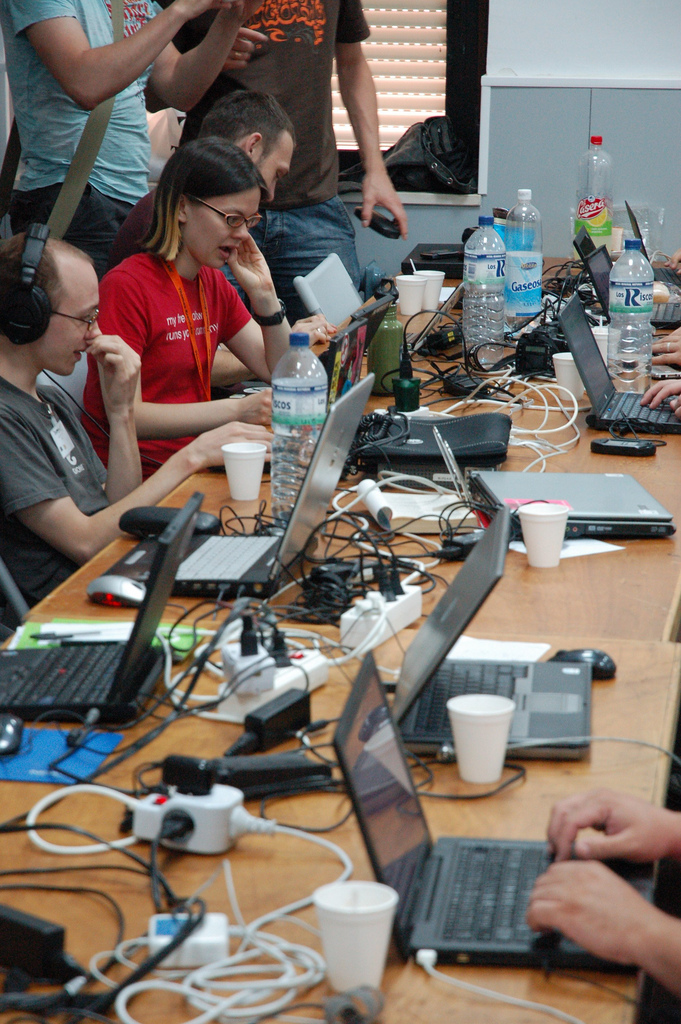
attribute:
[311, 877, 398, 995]
styrofoam cup — small, white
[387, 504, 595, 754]
laptop computer — black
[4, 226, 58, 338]
headphones — black, large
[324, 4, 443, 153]
window blinds — white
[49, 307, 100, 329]
eyeglasses — man's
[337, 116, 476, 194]
bag — black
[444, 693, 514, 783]
styrofoam — white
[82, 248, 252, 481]
tee shirt — orange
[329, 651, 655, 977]
computer — black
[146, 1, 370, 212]
shirt — black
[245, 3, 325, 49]
design — orange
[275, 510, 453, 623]
cords — black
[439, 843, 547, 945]
keys — black